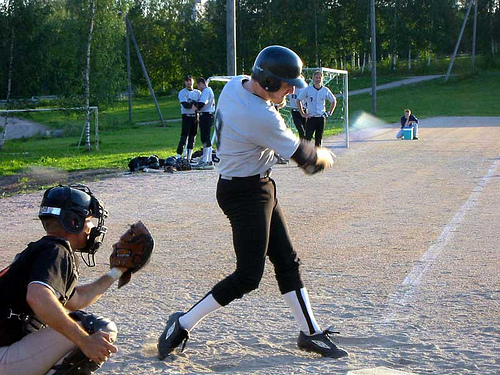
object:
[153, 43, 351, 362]
man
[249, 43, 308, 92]
helmet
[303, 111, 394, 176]
bat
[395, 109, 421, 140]
man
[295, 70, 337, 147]
man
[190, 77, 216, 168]
man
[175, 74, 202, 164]
man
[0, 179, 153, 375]
catcher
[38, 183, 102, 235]
helmet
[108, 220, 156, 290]
mitt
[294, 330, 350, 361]
cleet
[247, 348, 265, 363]
dirt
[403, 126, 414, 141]
pitcher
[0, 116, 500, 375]
ground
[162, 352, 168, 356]
toe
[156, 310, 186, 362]
shoe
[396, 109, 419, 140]
person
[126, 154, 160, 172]
bags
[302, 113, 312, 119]
hands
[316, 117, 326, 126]
hips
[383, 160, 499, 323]
line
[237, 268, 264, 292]
knee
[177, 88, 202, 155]
uniform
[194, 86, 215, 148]
uniform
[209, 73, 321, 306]
uniform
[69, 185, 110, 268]
face guard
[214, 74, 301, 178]
jersey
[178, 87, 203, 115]
jersey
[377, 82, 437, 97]
trail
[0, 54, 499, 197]
grass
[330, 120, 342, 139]
net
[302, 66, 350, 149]
goal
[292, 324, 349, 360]
shoes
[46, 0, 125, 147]
tree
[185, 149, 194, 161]
socks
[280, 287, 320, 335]
sock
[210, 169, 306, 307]
trouser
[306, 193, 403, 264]
sand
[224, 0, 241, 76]
post